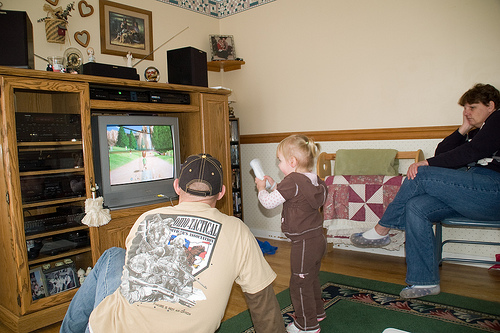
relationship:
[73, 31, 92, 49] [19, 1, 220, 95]
hearts hanging on wall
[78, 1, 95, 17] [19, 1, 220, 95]
heats hanging on wall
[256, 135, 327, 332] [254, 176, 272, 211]
girl has hand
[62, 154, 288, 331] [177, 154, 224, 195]
man has hat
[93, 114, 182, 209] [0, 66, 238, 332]
tv has stand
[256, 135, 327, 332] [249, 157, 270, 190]
child has controller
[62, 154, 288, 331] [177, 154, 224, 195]
man has cap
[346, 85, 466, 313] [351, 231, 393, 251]
woman wearing slipper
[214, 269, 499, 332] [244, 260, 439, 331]
rug on floor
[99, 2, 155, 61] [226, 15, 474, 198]
picture on wall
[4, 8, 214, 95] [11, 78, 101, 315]
stereo system on shelf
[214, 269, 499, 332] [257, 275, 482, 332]
rug on floor